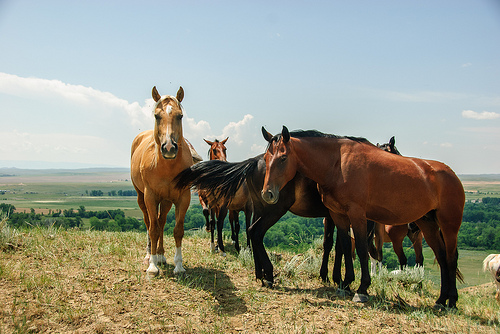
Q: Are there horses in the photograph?
A: Yes, there is a horse.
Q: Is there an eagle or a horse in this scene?
A: Yes, there is a horse.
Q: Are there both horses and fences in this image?
A: No, there is a horse but no fences.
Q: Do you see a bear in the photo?
A: No, there are no bears.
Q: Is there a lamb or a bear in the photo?
A: No, there are no bears or lambs.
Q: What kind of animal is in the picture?
A: The animal is a horse.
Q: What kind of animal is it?
A: The animal is a horse.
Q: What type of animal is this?
A: This is a horse.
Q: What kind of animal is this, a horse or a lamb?
A: This is a horse.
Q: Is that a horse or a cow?
A: That is a horse.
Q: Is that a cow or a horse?
A: That is a horse.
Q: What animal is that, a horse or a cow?
A: That is a horse.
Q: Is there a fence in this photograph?
A: No, there are no fences.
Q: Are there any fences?
A: No, there are no fences.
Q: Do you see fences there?
A: No, there are no fences.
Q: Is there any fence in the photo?
A: No, there are no fences.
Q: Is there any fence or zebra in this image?
A: No, there are no fences or zebras.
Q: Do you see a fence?
A: No, there are no fences.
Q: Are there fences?
A: No, there are no fences.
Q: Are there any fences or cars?
A: No, there are no fences or cars.